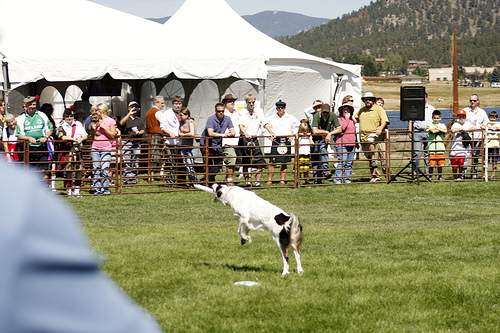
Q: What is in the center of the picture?
A: A dog.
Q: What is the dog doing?
A: Catching a frisbee.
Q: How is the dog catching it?
A: In its teeth.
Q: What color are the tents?
A: White.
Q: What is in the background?
A: Mountains and sky.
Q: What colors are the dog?
A: White and black.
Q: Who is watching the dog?
A: A crowd of people.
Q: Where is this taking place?
A: Outside in the park.